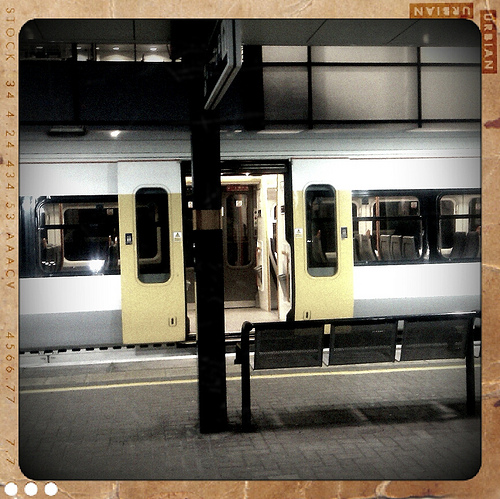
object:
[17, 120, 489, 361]
car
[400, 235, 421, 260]
seat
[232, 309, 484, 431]
bench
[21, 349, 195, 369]
beam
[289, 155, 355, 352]
door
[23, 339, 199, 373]
spacer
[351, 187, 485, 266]
window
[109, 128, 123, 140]
light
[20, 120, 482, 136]
ceiling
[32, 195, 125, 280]
window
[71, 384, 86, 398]
tile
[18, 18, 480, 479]
terminal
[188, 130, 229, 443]
pole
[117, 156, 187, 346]
door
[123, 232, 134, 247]
handle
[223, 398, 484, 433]
shadow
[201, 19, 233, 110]
sign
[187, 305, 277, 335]
floor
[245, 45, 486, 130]
frame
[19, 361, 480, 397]
line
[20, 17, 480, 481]
station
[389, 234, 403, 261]
seat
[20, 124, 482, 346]
subway